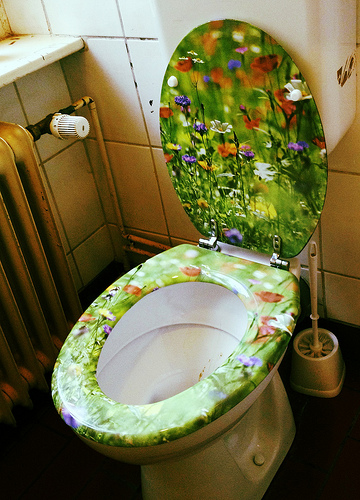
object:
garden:
[139, 34, 312, 281]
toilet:
[78, 89, 314, 499]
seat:
[55, 231, 304, 434]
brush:
[298, 239, 337, 338]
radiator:
[10, 97, 76, 422]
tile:
[93, 25, 177, 234]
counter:
[1, 14, 81, 72]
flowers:
[160, 33, 328, 259]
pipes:
[27, 97, 167, 263]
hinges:
[190, 241, 289, 273]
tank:
[161, 7, 359, 155]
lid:
[165, 28, 325, 261]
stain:
[168, 313, 262, 415]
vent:
[52, 111, 95, 151]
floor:
[295, 400, 357, 499]